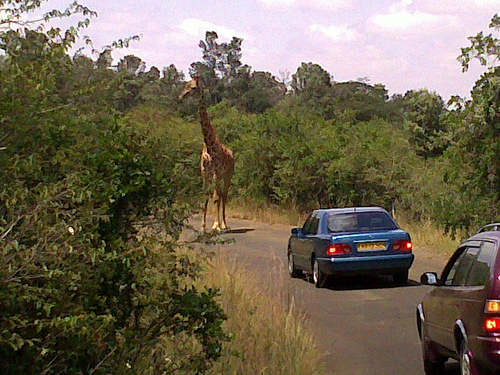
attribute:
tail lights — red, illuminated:
[326, 237, 412, 257]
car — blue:
[282, 201, 412, 288]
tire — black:
[280, 247, 300, 274]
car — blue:
[271, 179, 445, 314]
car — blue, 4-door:
[261, 201, 434, 296]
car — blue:
[289, 197, 413, 283]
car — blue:
[276, 180, 421, 298]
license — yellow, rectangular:
[353, 240, 392, 252]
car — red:
[398, 221, 496, 373]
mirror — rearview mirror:
[287, 223, 305, 241]